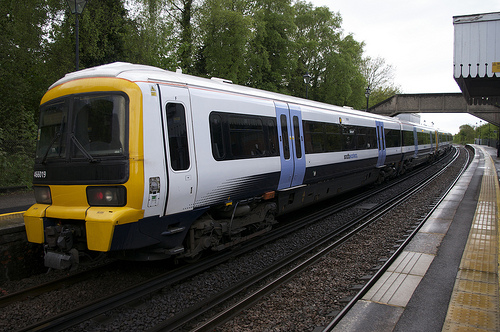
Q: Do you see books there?
A: No, there are no books.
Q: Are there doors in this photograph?
A: Yes, there are doors.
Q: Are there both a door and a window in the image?
A: Yes, there are both a door and a window.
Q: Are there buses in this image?
A: No, there are no buses.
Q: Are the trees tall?
A: Yes, the trees are tall.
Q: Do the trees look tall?
A: Yes, the trees are tall.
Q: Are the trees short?
A: No, the trees are tall.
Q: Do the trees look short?
A: No, the trees are tall.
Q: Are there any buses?
A: No, there are no buses.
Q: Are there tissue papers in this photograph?
A: No, there are no tissue papers.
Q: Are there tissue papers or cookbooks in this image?
A: No, there are no tissue papers or cookbooks.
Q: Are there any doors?
A: Yes, there is a door.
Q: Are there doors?
A: Yes, there is a door.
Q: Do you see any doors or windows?
A: Yes, there is a door.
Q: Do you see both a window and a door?
A: Yes, there are both a door and a window.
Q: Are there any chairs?
A: No, there are no chairs.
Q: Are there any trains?
A: Yes, there is a train.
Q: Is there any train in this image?
A: Yes, there is a train.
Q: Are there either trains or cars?
A: Yes, there is a train.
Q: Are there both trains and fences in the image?
A: No, there is a train but no fences.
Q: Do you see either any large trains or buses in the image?
A: Yes, there is a large train.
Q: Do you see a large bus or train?
A: Yes, there is a large train.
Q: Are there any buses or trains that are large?
A: Yes, the train is large.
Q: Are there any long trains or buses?
A: Yes, there is a long train.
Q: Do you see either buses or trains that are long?
A: Yes, the train is long.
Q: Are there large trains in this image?
A: Yes, there is a large train.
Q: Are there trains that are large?
A: Yes, there is a train that is large.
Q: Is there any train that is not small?
A: Yes, there is a large train.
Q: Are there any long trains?
A: Yes, there is a long train.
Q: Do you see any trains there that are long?
A: Yes, there is a train that is long.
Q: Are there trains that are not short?
A: Yes, there is a long train.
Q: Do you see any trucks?
A: No, there are no trucks.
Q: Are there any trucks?
A: No, there are no trucks.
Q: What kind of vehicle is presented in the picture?
A: The vehicle is a train.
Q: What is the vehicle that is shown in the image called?
A: The vehicle is a train.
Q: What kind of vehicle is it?
A: The vehicle is a train.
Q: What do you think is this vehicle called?
A: This is a train.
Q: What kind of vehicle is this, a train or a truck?
A: This is a train.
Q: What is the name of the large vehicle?
A: The vehicle is a train.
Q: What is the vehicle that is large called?
A: The vehicle is a train.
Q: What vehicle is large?
A: The vehicle is a train.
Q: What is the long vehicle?
A: The vehicle is a train.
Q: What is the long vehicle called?
A: The vehicle is a train.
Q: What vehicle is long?
A: The vehicle is a train.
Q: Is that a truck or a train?
A: That is a train.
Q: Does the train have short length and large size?
A: No, the train is large but long.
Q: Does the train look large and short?
A: No, the train is large but long.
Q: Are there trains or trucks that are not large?
A: No, there is a train but it is large.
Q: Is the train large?
A: Yes, the train is large.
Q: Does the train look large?
A: Yes, the train is large.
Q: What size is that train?
A: The train is large.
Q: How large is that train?
A: The train is large.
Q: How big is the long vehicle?
A: The train is large.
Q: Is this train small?
A: No, the train is large.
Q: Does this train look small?
A: No, the train is large.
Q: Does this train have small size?
A: No, the train is large.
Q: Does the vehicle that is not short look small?
A: No, the train is large.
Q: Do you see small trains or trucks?
A: No, there is a train but it is large.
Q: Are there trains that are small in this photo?
A: No, there is a train but it is large.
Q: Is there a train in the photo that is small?
A: No, there is a train but it is large.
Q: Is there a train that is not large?
A: No, there is a train but it is large.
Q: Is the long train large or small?
A: The train is large.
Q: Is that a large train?
A: Yes, that is a large train.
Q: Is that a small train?
A: No, that is a large train.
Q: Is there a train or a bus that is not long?
A: No, there is a train but it is long.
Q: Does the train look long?
A: Yes, the train is long.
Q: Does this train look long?
A: Yes, the train is long.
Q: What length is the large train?
A: The train is long.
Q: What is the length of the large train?
A: The train is long.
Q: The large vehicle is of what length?
A: The train is long.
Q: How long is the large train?
A: The train is long.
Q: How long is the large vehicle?
A: The train is long.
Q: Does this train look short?
A: No, the train is long.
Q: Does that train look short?
A: No, the train is long.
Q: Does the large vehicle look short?
A: No, the train is long.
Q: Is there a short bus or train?
A: No, there is a train but it is long.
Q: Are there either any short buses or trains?
A: No, there is a train but it is long.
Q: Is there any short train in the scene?
A: No, there is a train but it is long.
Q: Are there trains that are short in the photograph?
A: No, there is a train but it is long.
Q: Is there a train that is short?
A: No, there is a train but it is long.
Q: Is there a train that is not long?
A: No, there is a train but it is long.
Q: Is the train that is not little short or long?
A: The train is long.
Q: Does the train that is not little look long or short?
A: The train is long.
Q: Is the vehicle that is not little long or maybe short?
A: The train is long.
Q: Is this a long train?
A: Yes, this is a long train.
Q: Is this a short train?
A: No, this is a long train.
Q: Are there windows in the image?
A: Yes, there are windows.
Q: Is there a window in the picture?
A: Yes, there are windows.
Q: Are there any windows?
A: Yes, there are windows.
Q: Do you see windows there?
A: Yes, there are windows.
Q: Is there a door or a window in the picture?
A: Yes, there are windows.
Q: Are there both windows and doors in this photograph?
A: Yes, there are both windows and doors.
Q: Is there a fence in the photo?
A: No, there are no fences.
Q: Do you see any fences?
A: No, there are no fences.